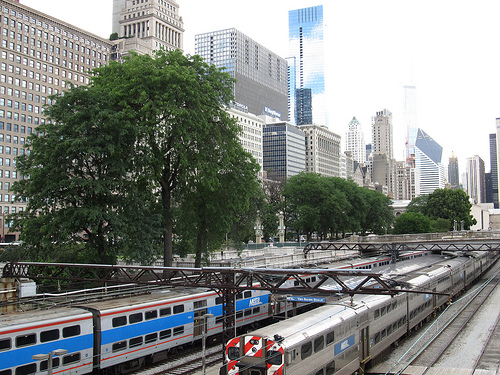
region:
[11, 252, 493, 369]
commuter trains on tracks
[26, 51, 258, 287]
large tree beside tracks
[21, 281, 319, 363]
double deck passenger cars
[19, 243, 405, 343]
overhead signal supports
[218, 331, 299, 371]
red and white caution stripes on engine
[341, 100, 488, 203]
tall buildings in the city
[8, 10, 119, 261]
wall of windows on building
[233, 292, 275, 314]
train logo on train car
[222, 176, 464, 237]
trees lining city street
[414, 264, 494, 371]
empty track beside train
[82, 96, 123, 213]
green leaves on trees.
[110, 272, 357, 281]
metal framework above trains.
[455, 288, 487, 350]
empty train tracks.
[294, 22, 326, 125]
tall building behind trains.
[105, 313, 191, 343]
blue line across train.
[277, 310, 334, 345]
silver top of train car.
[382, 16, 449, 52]
white clouds in sky.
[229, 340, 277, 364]
red and white stripes.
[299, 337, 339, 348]
windows alongside the train.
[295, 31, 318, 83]
reflection on side of building.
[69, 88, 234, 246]
this is a tree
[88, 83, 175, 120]
the tree has green leaves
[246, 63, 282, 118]
this is a building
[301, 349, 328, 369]
this is a train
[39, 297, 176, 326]
the train is long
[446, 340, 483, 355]
this is a railway line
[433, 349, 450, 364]
the lines are made of metal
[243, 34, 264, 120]
this is a tall building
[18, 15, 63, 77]
the building has many windows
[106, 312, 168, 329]
the train is made of metal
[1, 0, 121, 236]
tall building with multiple windows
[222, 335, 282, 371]
red and white stripes on front of train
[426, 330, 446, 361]
section of train tracks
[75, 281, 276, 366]
train car with blue stripe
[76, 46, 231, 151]
tree with green leaves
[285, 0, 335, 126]
side of building with reflection of sky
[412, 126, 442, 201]
building with a sloping roof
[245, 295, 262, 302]
logo on side of train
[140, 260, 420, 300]
black scaffolding over train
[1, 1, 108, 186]
building with glass windows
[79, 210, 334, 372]
Trains parked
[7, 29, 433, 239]
The city next to the terminal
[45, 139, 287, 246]
Trees along the train tracks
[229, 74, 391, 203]
Buildings in the city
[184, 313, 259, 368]
A train cart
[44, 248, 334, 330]
Lots of train cars with passengers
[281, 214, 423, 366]
Train tracks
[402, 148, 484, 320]
Trees and trains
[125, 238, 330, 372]
Lots of train cars on the tracks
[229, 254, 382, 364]
People travel on train